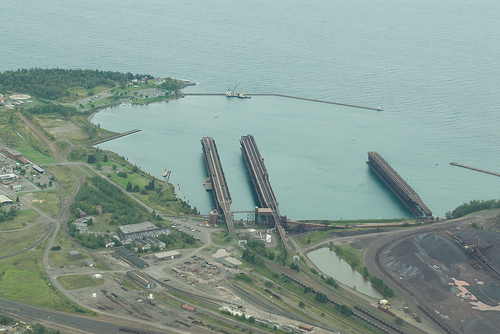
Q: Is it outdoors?
A: Yes, it is outdoors.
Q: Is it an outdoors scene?
A: Yes, it is outdoors.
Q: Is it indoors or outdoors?
A: It is outdoors.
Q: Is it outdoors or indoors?
A: It is outdoors.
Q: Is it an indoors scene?
A: No, it is outdoors.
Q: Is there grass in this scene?
A: Yes, there is grass.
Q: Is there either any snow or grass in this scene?
A: Yes, there is grass.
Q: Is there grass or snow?
A: Yes, there is grass.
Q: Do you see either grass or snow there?
A: Yes, there is grass.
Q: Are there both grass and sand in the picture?
A: No, there is grass but no sand.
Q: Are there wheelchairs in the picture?
A: No, there are no wheelchairs.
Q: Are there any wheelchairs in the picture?
A: No, there are no wheelchairs.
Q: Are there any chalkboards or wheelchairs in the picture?
A: No, there are no wheelchairs or chalkboards.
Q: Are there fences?
A: No, there are no fences.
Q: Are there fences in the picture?
A: No, there are no fences.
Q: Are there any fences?
A: No, there are no fences.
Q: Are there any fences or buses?
A: No, there are no fences or buses.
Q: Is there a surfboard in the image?
A: No, there are no surfboards.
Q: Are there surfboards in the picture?
A: No, there are no surfboards.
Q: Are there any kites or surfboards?
A: No, there are no surfboards or kites.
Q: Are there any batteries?
A: No, there are no batteries.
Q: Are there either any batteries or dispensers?
A: No, there are no batteries or dispensers.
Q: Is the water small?
A: Yes, the water is small.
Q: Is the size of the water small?
A: Yes, the water is small.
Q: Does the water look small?
A: Yes, the water is small.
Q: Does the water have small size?
A: Yes, the water is small.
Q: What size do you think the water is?
A: The water is small.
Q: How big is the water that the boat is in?
A: The water is small.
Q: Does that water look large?
A: No, the water is small.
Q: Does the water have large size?
A: No, the water is small.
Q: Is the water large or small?
A: The water is small.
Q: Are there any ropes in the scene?
A: No, there are no ropes.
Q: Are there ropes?
A: No, there are no ropes.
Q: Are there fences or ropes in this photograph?
A: No, there are no ropes or fences.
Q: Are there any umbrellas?
A: No, there are no umbrellas.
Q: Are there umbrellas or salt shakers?
A: No, there are no umbrellas or salt shakers.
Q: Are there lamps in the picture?
A: No, there are no lamps.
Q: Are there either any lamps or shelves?
A: No, there are no lamps or shelves.